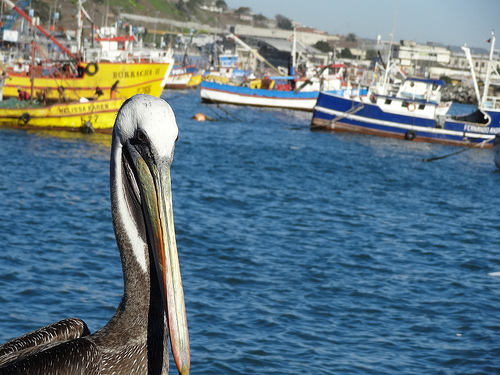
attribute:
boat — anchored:
[2, 41, 129, 136]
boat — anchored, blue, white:
[197, 21, 370, 110]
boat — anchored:
[81, 20, 177, 88]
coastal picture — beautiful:
[2, 0, 482, 370]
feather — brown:
[60, 320, 75, 336]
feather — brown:
[34, 330, 53, 341]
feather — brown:
[15, 338, 35, 349]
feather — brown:
[132, 344, 142, 356]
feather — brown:
[97, 350, 116, 357]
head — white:
[112, 90, 183, 171]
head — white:
[113, 91, 183, 161]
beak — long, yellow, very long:
[128, 142, 193, 372]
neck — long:
[109, 131, 169, 340]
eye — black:
[135, 128, 147, 143]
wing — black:
[1, 315, 88, 365]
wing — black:
[1, 338, 105, 373]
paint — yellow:
[1, 94, 128, 137]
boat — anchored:
[2, 1, 172, 101]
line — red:
[1, 76, 165, 91]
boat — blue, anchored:
[308, 29, 483, 149]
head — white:
[63, 82, 212, 232]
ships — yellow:
[46, 47, 220, 128]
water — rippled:
[200, 144, 396, 324]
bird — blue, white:
[62, 82, 214, 308]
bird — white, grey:
[56, 93, 270, 364]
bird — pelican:
[71, 96, 241, 341]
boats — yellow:
[16, 46, 165, 136]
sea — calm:
[11, 30, 160, 141]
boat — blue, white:
[309, 57, 492, 175]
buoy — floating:
[182, 100, 235, 140]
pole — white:
[467, 28, 495, 92]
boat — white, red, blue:
[190, 58, 342, 120]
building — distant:
[340, 35, 476, 92]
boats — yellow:
[24, 51, 179, 151]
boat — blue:
[306, 47, 489, 197]